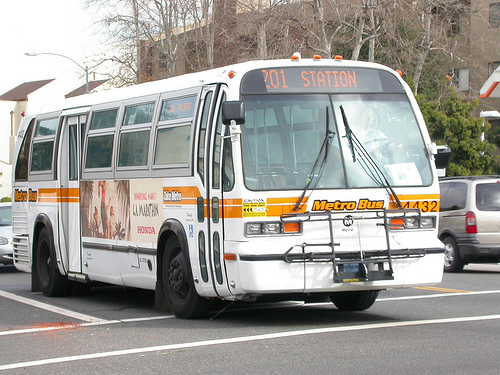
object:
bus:
[12, 58, 447, 318]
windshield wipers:
[338, 106, 403, 211]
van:
[436, 177, 497, 274]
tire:
[162, 232, 207, 318]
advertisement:
[80, 181, 162, 249]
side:
[17, 78, 234, 296]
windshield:
[239, 92, 434, 188]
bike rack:
[280, 205, 426, 284]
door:
[194, 85, 224, 297]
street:
[0, 208, 496, 374]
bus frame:
[83, 63, 439, 286]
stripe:
[162, 185, 202, 200]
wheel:
[32, 224, 63, 297]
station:
[300, 69, 360, 88]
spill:
[38, 321, 84, 335]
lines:
[224, 203, 241, 209]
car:
[1, 200, 14, 269]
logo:
[310, 198, 384, 210]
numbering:
[403, 201, 437, 213]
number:
[261, 70, 288, 90]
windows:
[153, 124, 192, 169]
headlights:
[246, 222, 264, 235]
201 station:
[260, 68, 360, 89]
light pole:
[82, 65, 89, 92]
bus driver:
[331, 104, 392, 171]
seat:
[322, 141, 396, 183]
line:
[414, 292, 456, 301]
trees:
[187, 0, 229, 69]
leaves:
[468, 156, 484, 171]